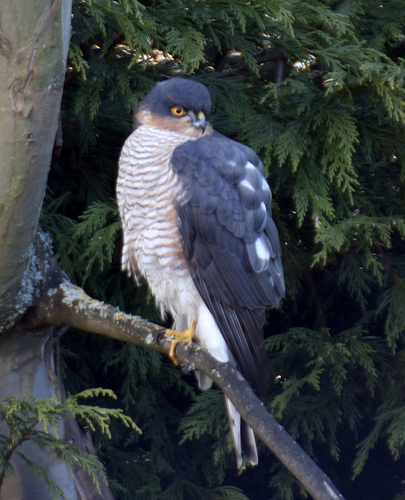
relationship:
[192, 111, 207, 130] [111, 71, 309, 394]
beak on bird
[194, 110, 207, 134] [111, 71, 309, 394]
beak on bird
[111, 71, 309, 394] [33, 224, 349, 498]
bird on branch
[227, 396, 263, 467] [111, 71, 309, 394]
feather on bird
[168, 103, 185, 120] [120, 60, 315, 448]
eye on bird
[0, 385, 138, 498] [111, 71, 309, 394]
green branch on bird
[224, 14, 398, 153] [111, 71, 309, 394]
tree behind bird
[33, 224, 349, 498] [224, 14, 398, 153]
branch on tree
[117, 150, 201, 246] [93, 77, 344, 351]
breast on bird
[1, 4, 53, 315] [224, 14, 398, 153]
tree trunk on tree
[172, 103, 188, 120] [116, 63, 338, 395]
eye on bird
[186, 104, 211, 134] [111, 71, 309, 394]
beak on bird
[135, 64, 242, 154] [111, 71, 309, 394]
head on bird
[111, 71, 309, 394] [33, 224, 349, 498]
bird sitting on branch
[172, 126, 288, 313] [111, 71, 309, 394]
wing on bird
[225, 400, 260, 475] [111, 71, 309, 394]
tail on bird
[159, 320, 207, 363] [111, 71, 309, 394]
foot on bird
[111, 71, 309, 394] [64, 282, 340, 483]
bird sitting on branch